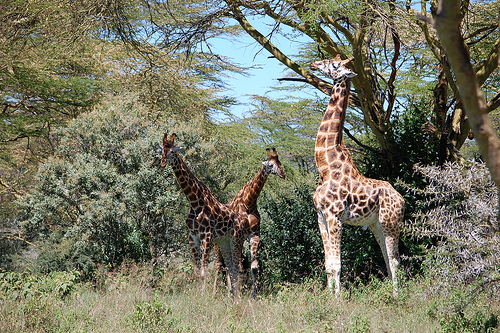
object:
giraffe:
[302, 53, 403, 301]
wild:
[0, 0, 499, 333]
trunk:
[430, 0, 499, 182]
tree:
[369, 0, 499, 188]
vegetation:
[392, 157, 499, 333]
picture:
[0, 0, 496, 333]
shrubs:
[31, 97, 225, 294]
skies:
[0, 0, 499, 146]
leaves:
[317, 14, 322, 20]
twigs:
[249, 34, 271, 61]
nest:
[391, 14, 444, 46]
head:
[308, 51, 365, 81]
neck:
[309, 77, 361, 182]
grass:
[125, 299, 195, 333]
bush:
[399, 154, 498, 303]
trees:
[0, 0, 112, 169]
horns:
[339, 56, 355, 66]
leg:
[326, 212, 343, 294]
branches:
[222, 0, 362, 107]